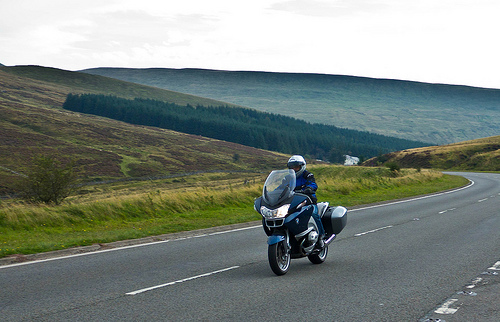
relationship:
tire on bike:
[255, 242, 299, 280] [253, 169, 347, 276]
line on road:
[119, 258, 241, 303] [0, 170, 500, 322]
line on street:
[351, 214, 398, 238] [367, 248, 442, 275]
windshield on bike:
[259, 167, 301, 212] [253, 169, 347, 276]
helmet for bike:
[287, 151, 308, 175] [253, 169, 347, 276]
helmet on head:
[287, 151, 308, 175] [288, 162, 304, 172]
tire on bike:
[268, 240, 292, 275] [253, 169, 347, 276]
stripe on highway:
[359, 189, 486, 251] [0, 160, 499, 320]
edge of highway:
[4, 226, 239, 269] [15, 146, 497, 319]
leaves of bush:
[9, 156, 89, 212] [22, 147, 77, 203]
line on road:
[353, 224, 393, 236] [433, 208, 475, 275]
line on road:
[435, 200, 457, 219] [0, 170, 498, 320]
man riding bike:
[278, 149, 325, 241] [253, 169, 347, 276]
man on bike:
[262, 155, 325, 249] [252, 167, 350, 272]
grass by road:
[0, 63, 500, 259] [0, 170, 498, 320]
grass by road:
[5, 56, 498, 238] [0, 170, 498, 320]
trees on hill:
[63, 91, 437, 163] [3, 61, 434, 193]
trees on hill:
[63, 91, 437, 163] [0, 62, 337, 201]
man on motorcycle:
[262, 155, 325, 249] [248, 182, 324, 267]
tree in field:
[12, 152, 85, 206] [2, 67, 469, 267]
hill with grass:
[3, 60, 351, 230] [5, 198, 91, 233]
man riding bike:
[262, 155, 325, 249] [253, 169, 347, 276]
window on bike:
[258, 166, 300, 208] [253, 169, 347, 276]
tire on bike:
[313, 250, 329, 262] [253, 169, 347, 276]